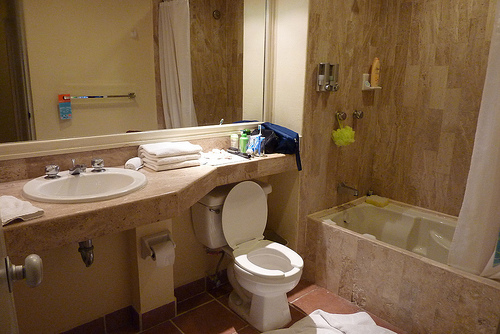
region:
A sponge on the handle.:
[337, 109, 359, 153]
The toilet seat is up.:
[216, 184, 277, 246]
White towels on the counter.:
[134, 137, 199, 183]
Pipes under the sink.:
[58, 237, 113, 274]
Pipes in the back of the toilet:
[200, 247, 222, 290]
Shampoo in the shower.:
[358, 47, 393, 101]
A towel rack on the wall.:
[59, 73, 154, 114]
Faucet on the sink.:
[47, 155, 135, 182]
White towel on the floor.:
[297, 298, 385, 328]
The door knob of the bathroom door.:
[3, 234, 38, 291]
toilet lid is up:
[217, 179, 281, 243]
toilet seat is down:
[235, 235, 310, 285]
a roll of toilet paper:
[148, 235, 183, 271]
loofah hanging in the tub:
[333, 108, 355, 149]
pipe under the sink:
[73, 234, 98, 266]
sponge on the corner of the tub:
[366, 187, 391, 208]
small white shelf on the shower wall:
[363, 84, 382, 92]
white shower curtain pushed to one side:
[155, 3, 211, 134]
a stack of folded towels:
[140, 137, 207, 174]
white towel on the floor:
[256, 305, 411, 332]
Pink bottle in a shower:
[369, 57, 382, 86]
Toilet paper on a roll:
[133, 230, 177, 265]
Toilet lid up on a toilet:
[221, 181, 268, 245]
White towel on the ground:
[260, 308, 407, 330]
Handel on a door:
[3, 254, 44, 288]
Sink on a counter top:
[19, 160, 147, 199]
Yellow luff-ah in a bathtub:
[331, 111, 355, 147]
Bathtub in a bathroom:
[306, 192, 499, 332]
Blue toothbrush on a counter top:
[254, 125, 265, 154]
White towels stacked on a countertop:
[135, 138, 205, 167]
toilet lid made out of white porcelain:
[214, 173, 274, 244]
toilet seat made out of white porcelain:
[230, 235, 304, 282]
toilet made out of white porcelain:
[191, 179, 302, 332]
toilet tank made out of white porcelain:
[191, 191, 224, 247]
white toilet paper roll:
[144, 227, 179, 269]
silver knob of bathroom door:
[7, 248, 39, 295]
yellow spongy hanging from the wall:
[328, 107, 357, 147]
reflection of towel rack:
[56, 82, 136, 107]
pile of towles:
[140, 128, 208, 178]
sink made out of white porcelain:
[31, 162, 139, 214]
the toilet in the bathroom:
[189, 177, 303, 330]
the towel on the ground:
[258, 308, 398, 332]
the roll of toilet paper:
[150, 239, 175, 266]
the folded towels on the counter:
[138, 140, 202, 170]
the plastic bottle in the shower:
[370, 56, 381, 86]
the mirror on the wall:
[0, 0, 275, 160]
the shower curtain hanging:
[447, 1, 499, 280]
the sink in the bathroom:
[22, 157, 146, 204]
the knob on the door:
[3, 253, 44, 293]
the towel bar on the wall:
[62, 91, 135, 100]